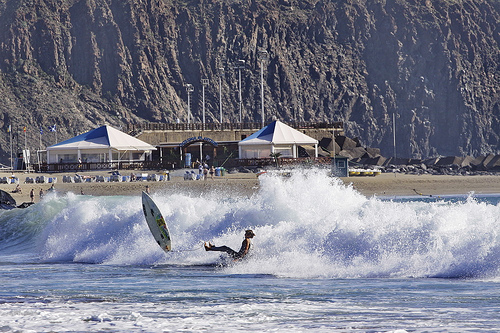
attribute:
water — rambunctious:
[3, 193, 498, 331]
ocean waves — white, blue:
[410, 198, 497, 244]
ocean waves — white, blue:
[334, 297, 391, 328]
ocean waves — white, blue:
[89, 301, 151, 328]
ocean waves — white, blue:
[79, 207, 129, 244]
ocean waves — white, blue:
[57, 282, 109, 304]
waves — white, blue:
[181, 271, 211, 304]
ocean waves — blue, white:
[47, 194, 462, 290]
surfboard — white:
[140, 191, 172, 256]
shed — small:
[310, 159, 355, 180]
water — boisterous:
[48, 182, 452, 219]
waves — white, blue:
[312, 252, 434, 295]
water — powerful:
[0, 160, 499, 332]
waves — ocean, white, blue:
[325, 179, 496, 319]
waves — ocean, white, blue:
[299, 164, 499, 286]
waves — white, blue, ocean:
[0, 165, 498, 282]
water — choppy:
[15, 206, 498, 325]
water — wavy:
[4, 177, 499, 328]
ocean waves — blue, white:
[314, 191, 497, 278]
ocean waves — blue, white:
[258, 170, 348, 231]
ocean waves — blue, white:
[40, 190, 151, 262]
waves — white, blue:
[308, 157, 469, 296]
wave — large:
[0, 170, 495, 282]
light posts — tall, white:
[177, 48, 267, 123]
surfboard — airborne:
[138, 189, 173, 255]